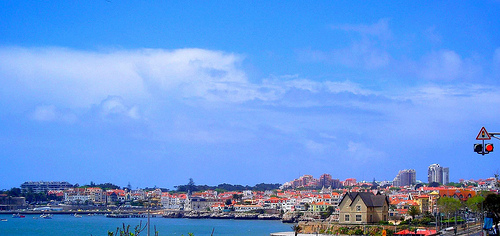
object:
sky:
[0, 0, 500, 194]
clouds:
[0, 45, 499, 155]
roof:
[107, 188, 126, 197]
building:
[104, 187, 122, 204]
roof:
[314, 192, 339, 199]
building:
[309, 196, 331, 216]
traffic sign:
[472, 126, 500, 156]